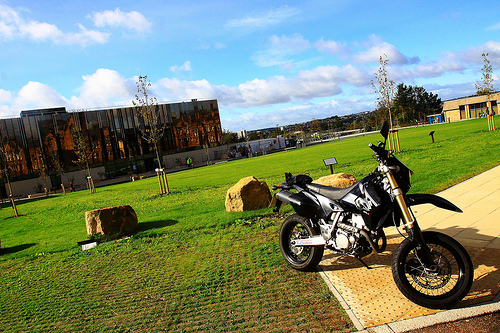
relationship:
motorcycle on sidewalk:
[270, 119, 484, 310] [289, 161, 499, 332]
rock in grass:
[86, 205, 142, 242] [0, 116, 500, 332]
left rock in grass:
[227, 175, 282, 212] [0, 116, 500, 332]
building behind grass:
[0, 99, 243, 203] [0, 116, 500, 332]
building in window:
[0, 99, 227, 199] [37, 113, 86, 174]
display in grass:
[321, 157, 342, 175] [0, 116, 500, 332]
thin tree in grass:
[132, 75, 181, 195] [0, 116, 500, 332]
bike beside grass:
[270, 119, 484, 310] [0, 116, 500, 332]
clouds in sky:
[1, 8, 155, 50] [5, 0, 499, 132]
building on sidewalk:
[0, 99, 243, 203] [0, 115, 498, 206]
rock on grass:
[86, 205, 142, 242] [0, 116, 500, 332]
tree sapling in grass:
[132, 75, 181, 195] [0, 116, 500, 332]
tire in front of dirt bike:
[388, 229, 473, 305] [270, 119, 484, 310]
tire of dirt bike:
[388, 229, 473, 305] [270, 119, 484, 310]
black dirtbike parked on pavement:
[270, 119, 484, 310] [289, 161, 499, 332]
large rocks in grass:
[227, 175, 282, 212] [0, 116, 500, 332]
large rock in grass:
[227, 175, 282, 212] [0, 116, 500, 332]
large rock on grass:
[227, 175, 282, 212] [0, 116, 500, 332]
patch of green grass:
[31, 209, 76, 244] [0, 116, 500, 332]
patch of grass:
[31, 209, 76, 244] [0, 116, 500, 332]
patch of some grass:
[39, 209, 76, 244] [0, 116, 500, 332]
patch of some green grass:
[31, 209, 76, 244] [0, 116, 500, 332]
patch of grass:
[39, 209, 76, 244] [0, 116, 500, 332]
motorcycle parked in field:
[270, 119, 484, 310] [0, 116, 500, 332]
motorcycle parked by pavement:
[270, 119, 484, 310] [289, 161, 499, 332]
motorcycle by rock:
[270, 119, 484, 310] [86, 205, 142, 242]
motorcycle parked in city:
[270, 119, 484, 310] [3, 54, 500, 332]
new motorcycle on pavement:
[270, 119, 484, 310] [289, 161, 499, 332]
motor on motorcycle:
[277, 173, 323, 215] [270, 119, 484, 310]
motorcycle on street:
[270, 119, 484, 310] [289, 161, 499, 332]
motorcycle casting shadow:
[270, 119, 484, 310] [317, 224, 499, 308]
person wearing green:
[184, 157, 196, 168] [187, 157, 192, 165]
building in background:
[0, 99, 243, 203] [0, 0, 499, 202]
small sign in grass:
[321, 157, 342, 175] [0, 116, 500, 332]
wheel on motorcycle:
[277, 213, 332, 271] [270, 119, 484, 310]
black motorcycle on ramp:
[270, 119, 484, 310] [289, 161, 499, 332]